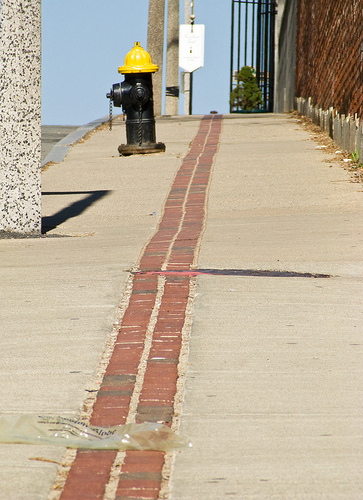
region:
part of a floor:
[235, 168, 271, 203]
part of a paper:
[127, 424, 147, 455]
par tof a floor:
[241, 439, 267, 476]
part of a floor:
[248, 439, 273, 477]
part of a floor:
[254, 425, 280, 454]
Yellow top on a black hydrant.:
[114, 40, 162, 77]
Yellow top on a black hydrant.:
[231, 55, 264, 93]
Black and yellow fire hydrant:
[107, 43, 166, 154]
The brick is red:
[57, 106, 222, 497]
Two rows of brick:
[61, 108, 225, 496]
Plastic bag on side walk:
[6, 402, 189, 460]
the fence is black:
[226, 0, 274, 114]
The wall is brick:
[298, 3, 358, 136]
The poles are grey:
[0, 2, 191, 232]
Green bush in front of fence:
[230, 65, 269, 110]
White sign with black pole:
[172, 14, 207, 119]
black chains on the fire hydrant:
[108, 73, 152, 146]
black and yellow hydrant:
[93, 33, 168, 172]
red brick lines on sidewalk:
[140, 284, 168, 381]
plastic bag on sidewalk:
[21, 392, 177, 468]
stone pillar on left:
[0, 12, 72, 253]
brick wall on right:
[278, 14, 359, 126]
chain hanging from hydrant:
[94, 97, 118, 129]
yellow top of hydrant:
[111, 41, 159, 77]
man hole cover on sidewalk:
[134, 246, 316, 286]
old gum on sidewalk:
[193, 468, 235, 497]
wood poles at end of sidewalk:
[163, 6, 179, 114]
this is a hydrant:
[108, 38, 161, 147]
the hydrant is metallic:
[112, 33, 162, 147]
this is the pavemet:
[209, 114, 324, 263]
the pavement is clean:
[257, 144, 323, 218]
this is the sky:
[50, 7, 109, 65]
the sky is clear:
[45, 3, 112, 66]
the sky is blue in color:
[55, 10, 97, 78]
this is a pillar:
[0, 93, 45, 141]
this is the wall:
[308, 14, 358, 86]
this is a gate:
[229, 0, 276, 86]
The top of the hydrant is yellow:
[99, 37, 173, 85]